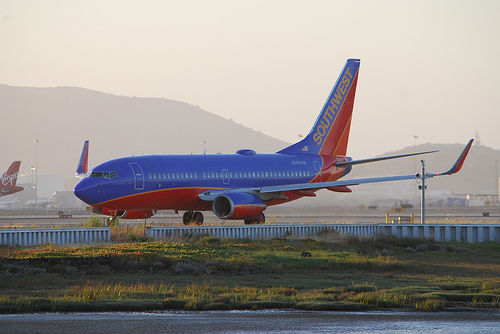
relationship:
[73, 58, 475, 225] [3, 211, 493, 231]
airplane on tarmac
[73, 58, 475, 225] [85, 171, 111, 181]
airplane has cockpit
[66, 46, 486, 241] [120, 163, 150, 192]
airplane has passenger door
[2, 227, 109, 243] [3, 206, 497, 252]
wall on side of building